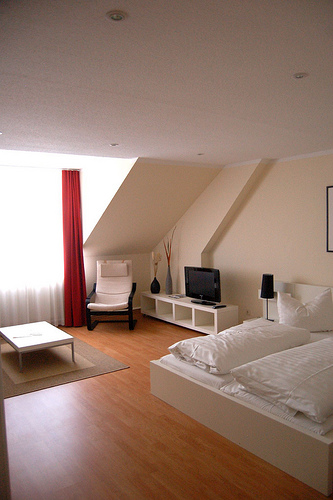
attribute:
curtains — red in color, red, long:
[63, 170, 88, 326]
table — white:
[0, 321, 75, 368]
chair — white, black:
[86, 261, 138, 329]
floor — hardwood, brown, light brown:
[1, 309, 321, 499]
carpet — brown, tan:
[2, 337, 127, 399]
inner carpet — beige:
[2, 338, 93, 384]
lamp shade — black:
[259, 275, 274, 298]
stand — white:
[140, 289, 238, 335]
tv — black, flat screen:
[184, 266, 220, 305]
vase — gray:
[165, 264, 173, 297]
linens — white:
[233, 330, 329, 432]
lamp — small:
[258, 273, 274, 322]